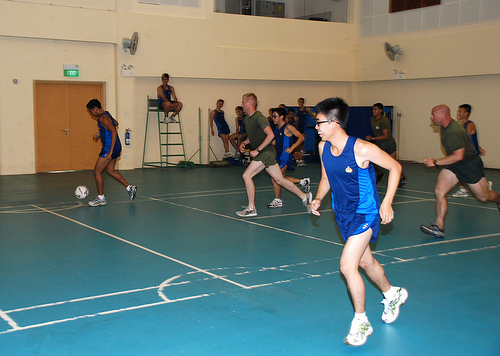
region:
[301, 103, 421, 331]
Asian man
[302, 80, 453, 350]
Asian man running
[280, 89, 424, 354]
Asian man wearing a blue uniform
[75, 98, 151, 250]
man kicking a soccer ball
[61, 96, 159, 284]
man in blue uniform kicking a soccer ball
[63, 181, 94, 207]
white soccer ball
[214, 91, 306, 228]
man in green uniform running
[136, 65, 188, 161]
woman on tall chair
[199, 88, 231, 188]
woman in blue leaning on wall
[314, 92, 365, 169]
glasses on man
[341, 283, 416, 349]
A white pair of shoes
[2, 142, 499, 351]
Indoor playing ground for soccer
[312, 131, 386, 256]
Blue jersey shirt and shorts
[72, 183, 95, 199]
Soccer ball inside the gym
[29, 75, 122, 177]
Brown doors leading into the gym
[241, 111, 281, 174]
Man in green shirt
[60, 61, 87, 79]
Green exit sign above door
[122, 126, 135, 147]
Blue fire extinguisher next to door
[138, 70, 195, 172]
Young man on top of green ladder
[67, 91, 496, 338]
Group of green and blue soccer players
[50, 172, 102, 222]
A ball being kicked.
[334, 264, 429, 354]
A pair of green and white sneakers.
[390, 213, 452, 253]
A black and gray shoe.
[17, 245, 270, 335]
White pattern on a blue gym floor.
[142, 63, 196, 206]
Person sitting on a tall chair.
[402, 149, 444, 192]
Black watch on a wrist.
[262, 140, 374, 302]
Dark blue and light blue outfit.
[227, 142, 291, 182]
A pair of green shorts.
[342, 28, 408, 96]
A loud speaker on the wall.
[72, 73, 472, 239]
People playing a sport.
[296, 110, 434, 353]
boy running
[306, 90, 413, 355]
boy in blue uniform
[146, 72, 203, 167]
man watching boys playing a game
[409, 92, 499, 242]
white man running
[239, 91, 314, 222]
man in green uniform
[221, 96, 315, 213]
two boys playing soccer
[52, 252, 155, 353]
in door gym floor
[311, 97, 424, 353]
boy in athletic grea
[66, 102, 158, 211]
boy kicking ball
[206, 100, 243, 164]
man watching game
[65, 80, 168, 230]
man dribbling soccer ball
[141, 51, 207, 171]
man sitting on a ladder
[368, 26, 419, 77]
wall mounted ceiling fan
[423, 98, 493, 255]
man with a shaved head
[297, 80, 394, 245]
man with glasses wearing blue shirt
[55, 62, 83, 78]
exit sign with green letters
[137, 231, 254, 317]
white lines on floor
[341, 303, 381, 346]
white tennis shoe/sneaker.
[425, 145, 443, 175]
wristwatch on man's arm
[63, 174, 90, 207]
white soccer ball